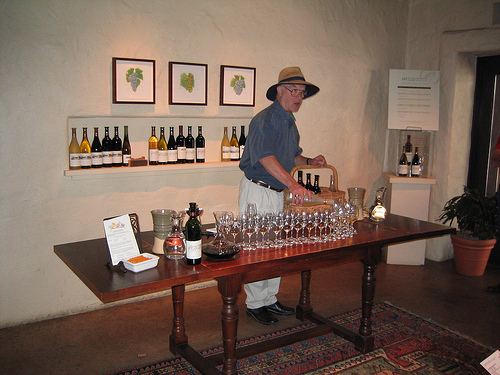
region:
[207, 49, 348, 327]
a man in a hat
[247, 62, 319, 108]
tan hat with black band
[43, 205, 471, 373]
a brown table over a rug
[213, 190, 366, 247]
several clear glasses on table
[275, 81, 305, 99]
glasses on man's face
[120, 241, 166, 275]
a little white container of pencils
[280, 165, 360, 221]
a tan wicker basket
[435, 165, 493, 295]
a plant in a pot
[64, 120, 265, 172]
bottles of wine on the wall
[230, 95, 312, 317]
a blue shirt and white pants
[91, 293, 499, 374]
Multi-colored carped on the floor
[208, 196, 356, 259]
Similar glasses clustered together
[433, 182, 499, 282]
Brown plastic container of room plant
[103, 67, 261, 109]
Three posters on the wall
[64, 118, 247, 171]
Row of long necked bottles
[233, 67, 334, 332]
Man standing behind glasses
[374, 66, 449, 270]
Three bottles on a stand at a corner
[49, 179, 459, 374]
Long table of tables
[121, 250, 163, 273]
White container containing orange substance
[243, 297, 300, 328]
Black pair of shoes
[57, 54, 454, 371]
man setting up a wine tasting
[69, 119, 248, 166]
varieties of wines about to be tasted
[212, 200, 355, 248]
glasses being poured with beverage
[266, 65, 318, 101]
man is wearing a hat and glasses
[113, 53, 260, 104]
decor of wine heritage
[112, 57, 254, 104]
different leaves from wine classifications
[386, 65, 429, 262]
display of wines with large poster with information and pricing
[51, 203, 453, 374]
fold out table is set up for tasting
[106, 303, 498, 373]
elegant rug displayed on floor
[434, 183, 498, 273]
decorative plant to side of room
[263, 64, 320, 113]
Old man in tan hat and glasses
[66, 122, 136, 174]
White and red wine bottles on shelf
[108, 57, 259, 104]
Three framed pictures of grapes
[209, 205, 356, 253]
Several wine glasses on wooden table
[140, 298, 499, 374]
Colorful rug on floor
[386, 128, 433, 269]
Three wine bottles on white pedestal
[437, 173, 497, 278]
Potted plant in orange planter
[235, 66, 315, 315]
Old man wearing blue shirt and white pants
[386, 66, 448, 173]
Rectangular white poster above wine bottles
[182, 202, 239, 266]
Bottle of wine and decanter on table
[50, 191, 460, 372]
a long wooden table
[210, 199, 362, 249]
several wine glasses on a table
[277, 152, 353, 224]
basket for carrying wine bottles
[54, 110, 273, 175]
shelf inset into the wall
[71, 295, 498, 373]
rug in the middle of the floor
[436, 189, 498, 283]
a potted leafy green plant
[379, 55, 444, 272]
a small standalone shelf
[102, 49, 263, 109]
decorative pictures on the wall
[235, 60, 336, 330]
a man in a wide brim hat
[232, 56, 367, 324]
a man pouring wine